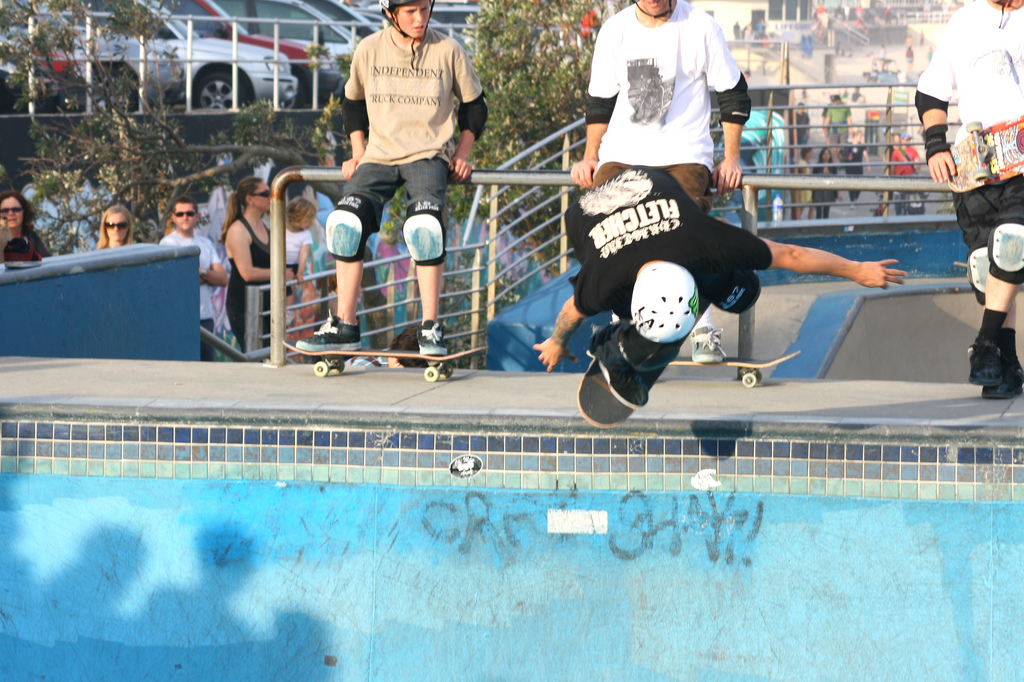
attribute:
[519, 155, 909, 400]
skateboarder — facing down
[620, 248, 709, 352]
helmet — mostly white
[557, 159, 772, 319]
shirt —  black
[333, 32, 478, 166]
shirt —  light brown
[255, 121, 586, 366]
gate —  gray,  metal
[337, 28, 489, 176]
shirt —  brown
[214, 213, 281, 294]
tank top —  black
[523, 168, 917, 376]
skateboarder —  white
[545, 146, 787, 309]
shirt —  black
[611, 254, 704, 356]
helmet — white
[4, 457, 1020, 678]
ramp — blue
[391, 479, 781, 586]
lettering — black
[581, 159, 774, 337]
shirt — light brown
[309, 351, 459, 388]
wheels — white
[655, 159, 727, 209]
shorts — brown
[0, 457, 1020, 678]
pool — blue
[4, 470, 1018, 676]
tiles — blue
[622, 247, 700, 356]
helmet — white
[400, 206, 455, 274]
knee pad — black, white, blue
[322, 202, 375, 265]
knee pad — black, white, blue